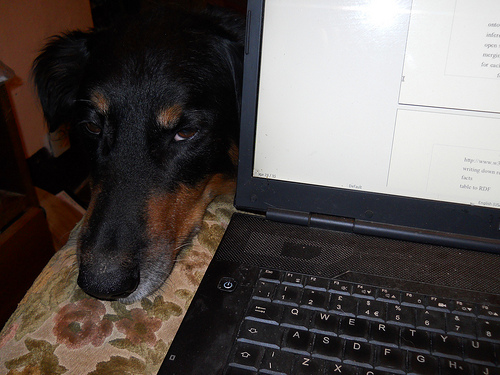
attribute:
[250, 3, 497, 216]
monitor — computer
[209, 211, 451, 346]
laptop — dusty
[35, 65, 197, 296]
dog — black , brown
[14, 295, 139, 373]
pattern — floral 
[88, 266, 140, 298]
nose — black